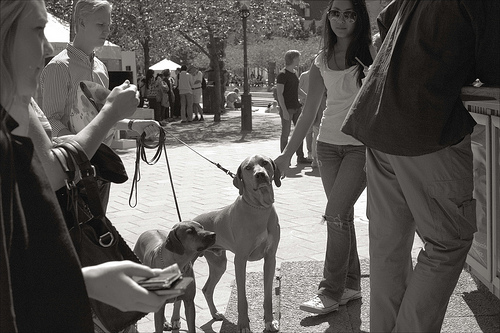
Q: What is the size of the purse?
A: Large.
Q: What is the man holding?
A: A leash.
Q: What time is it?
A: Afternoon.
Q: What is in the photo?
A: Two dogs.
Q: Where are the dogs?
A: In the photo.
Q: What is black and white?
A: The picture.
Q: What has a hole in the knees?
A: Jeans.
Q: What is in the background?
A: Trees.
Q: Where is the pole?
A: In the picture.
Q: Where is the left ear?
A: On the dog.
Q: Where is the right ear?
A: On the dog.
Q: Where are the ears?
A: On the dog.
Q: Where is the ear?
A: On the dog.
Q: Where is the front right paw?
A: On the dog.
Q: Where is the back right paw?
A: On the dog.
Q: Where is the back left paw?
A: On the dog.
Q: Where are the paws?
A: On the dog.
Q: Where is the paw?
A: On the dog.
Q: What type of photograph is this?
A: Black and white.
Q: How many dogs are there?
A: Two.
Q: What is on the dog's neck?
A: A leash.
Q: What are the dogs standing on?
A: A sidewalk.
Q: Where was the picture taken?
A: A park.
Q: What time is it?
A: Daytime.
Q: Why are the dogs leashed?
A: To guide them.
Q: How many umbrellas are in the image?
A: One.